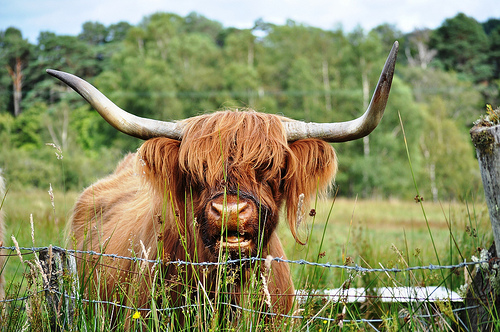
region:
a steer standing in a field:
[54, 81, 352, 303]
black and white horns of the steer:
[41, 54, 402, 135]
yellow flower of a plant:
[123, 307, 154, 327]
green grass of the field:
[353, 223, 410, 253]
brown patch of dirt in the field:
[363, 205, 444, 232]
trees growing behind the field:
[66, 16, 427, 115]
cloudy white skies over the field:
[222, 0, 367, 22]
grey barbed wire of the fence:
[261, 260, 486, 329]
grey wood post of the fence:
[463, 113, 498, 280]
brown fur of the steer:
[89, 193, 139, 253]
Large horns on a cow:
[35, 38, 400, 140]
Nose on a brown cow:
[208, 198, 253, 220]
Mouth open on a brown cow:
[205, 225, 260, 253]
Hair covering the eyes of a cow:
[171, 113, 281, 178]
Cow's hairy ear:
[279, 135, 334, 252]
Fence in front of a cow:
[1, 232, 499, 330]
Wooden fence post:
[468, 108, 496, 275]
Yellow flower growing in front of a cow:
[130, 306, 140, 320]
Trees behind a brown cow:
[1, 15, 496, 201]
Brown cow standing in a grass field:
[4, 185, 496, 294]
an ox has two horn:
[138, 94, 357, 329]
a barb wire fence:
[103, 217, 185, 280]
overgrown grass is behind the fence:
[78, 259, 272, 325]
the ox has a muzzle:
[191, 172, 333, 310]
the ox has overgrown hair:
[195, 103, 307, 233]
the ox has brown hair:
[185, 114, 355, 288]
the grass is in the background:
[141, 18, 400, 212]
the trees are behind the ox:
[7, 34, 100, 117]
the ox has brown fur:
[71, 118, 263, 328]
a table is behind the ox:
[278, 248, 436, 329]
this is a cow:
[39, 48, 427, 328]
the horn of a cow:
[278, 31, 419, 157]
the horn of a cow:
[36, 53, 213, 156]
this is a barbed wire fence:
[7, 240, 495, 327]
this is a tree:
[405, 60, 492, 188]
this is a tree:
[296, 58, 371, 186]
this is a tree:
[31, 95, 81, 190]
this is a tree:
[132, 26, 216, 173]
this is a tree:
[428, 5, 493, 108]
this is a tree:
[1, 43, 61, 150]